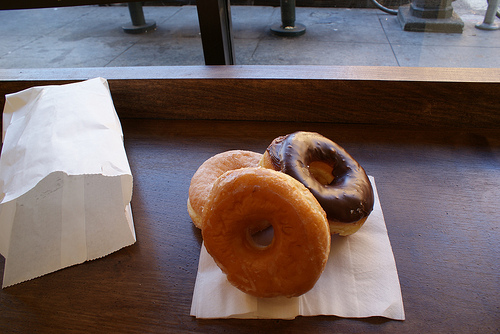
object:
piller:
[409, 0, 454, 18]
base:
[396, 0, 465, 34]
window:
[0, 0, 500, 79]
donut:
[260, 131, 375, 237]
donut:
[200, 166, 331, 298]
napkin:
[188, 175, 406, 320]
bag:
[0, 76, 138, 289]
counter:
[0, 65, 499, 334]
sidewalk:
[1, 5, 500, 69]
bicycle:
[371, 0, 400, 15]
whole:
[305, 161, 336, 186]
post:
[269, 1, 307, 37]